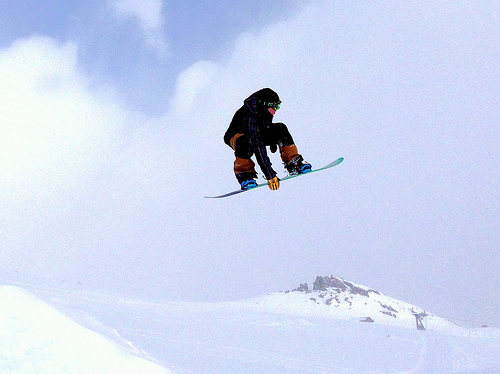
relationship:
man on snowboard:
[223, 86, 317, 190] [203, 155, 350, 200]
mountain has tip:
[278, 272, 465, 329] [308, 275, 357, 293]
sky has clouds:
[1, 2, 497, 249] [101, 0, 181, 63]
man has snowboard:
[223, 86, 317, 190] [203, 155, 350, 200]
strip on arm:
[250, 114, 272, 188] [253, 118, 266, 176]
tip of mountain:
[308, 275, 357, 293] [278, 272, 465, 329]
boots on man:
[241, 162, 317, 191] [223, 86, 317, 190]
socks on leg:
[231, 173, 260, 178] [233, 140, 256, 186]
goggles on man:
[272, 106, 281, 112] [223, 86, 317, 190]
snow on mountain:
[252, 289, 461, 332] [278, 272, 465, 329]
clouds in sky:
[101, 0, 181, 63] [1, 2, 497, 249]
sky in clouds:
[1, 2, 497, 249] [101, 0, 181, 63]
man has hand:
[223, 86, 317, 190] [264, 172, 284, 191]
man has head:
[223, 86, 317, 190] [254, 89, 278, 116]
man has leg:
[223, 86, 317, 190] [233, 140, 256, 186]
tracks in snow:
[1, 293, 498, 372] [94, 291, 284, 371]